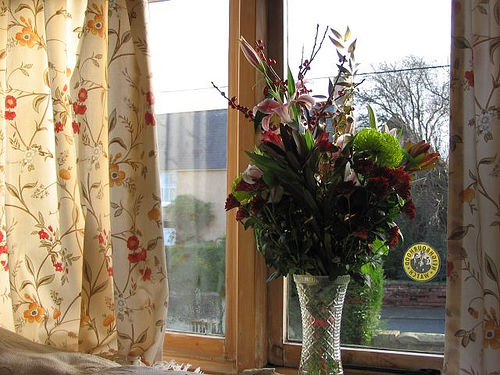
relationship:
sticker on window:
[402, 243, 440, 282] [239, 0, 452, 374]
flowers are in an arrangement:
[210, 22, 440, 374] [210, 22, 441, 285]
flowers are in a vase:
[210, 22, 440, 374] [293, 274, 352, 374]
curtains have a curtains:
[0, 0, 168, 366] [0, 0, 168, 366]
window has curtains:
[144, 1, 229, 338] [0, 0, 168, 366]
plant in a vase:
[210, 22, 440, 374] [293, 274, 352, 374]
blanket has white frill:
[1, 324, 208, 374] [135, 358, 207, 374]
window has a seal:
[144, 1, 229, 338] [141, 0, 240, 364]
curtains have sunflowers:
[0, 0, 168, 366] [16, 14, 109, 49]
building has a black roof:
[158, 169, 228, 249] [153, 108, 227, 170]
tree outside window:
[356, 51, 449, 282] [239, 0, 452, 374]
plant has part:
[210, 22, 440, 374] [284, 182, 298, 203]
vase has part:
[293, 274, 352, 374] [322, 316, 329, 330]